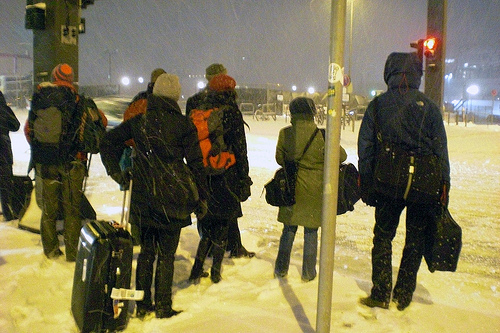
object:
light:
[121, 77, 129, 84]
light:
[138, 77, 144, 82]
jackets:
[25, 82, 103, 168]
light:
[424, 39, 437, 49]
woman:
[99, 69, 215, 319]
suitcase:
[70, 166, 144, 333]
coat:
[101, 91, 204, 229]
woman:
[269, 94, 350, 276]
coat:
[276, 114, 348, 226]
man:
[339, 47, 458, 315]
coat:
[354, 47, 450, 208]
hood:
[384, 51, 424, 90]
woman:
[168, 66, 256, 287]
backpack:
[181, 106, 235, 175]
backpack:
[336, 159, 362, 215]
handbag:
[261, 165, 298, 207]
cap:
[50, 62, 75, 83]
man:
[24, 60, 97, 260]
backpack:
[75, 96, 111, 153]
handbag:
[139, 109, 208, 221]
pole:
[312, 1, 352, 333]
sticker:
[327, 59, 353, 87]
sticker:
[327, 83, 335, 98]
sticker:
[328, 109, 338, 116]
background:
[0, 32, 499, 132]